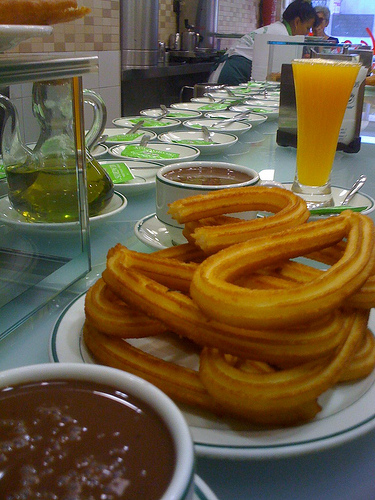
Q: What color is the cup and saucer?
A: White with a blue line.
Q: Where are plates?
A: On a table.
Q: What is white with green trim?
A: Plates.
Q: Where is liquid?
A: In a tall glass.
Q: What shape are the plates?
A: Round.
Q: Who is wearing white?
A: A woman.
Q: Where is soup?
A: In bowls.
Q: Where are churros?
A: On the plate.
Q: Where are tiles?
A: On the wall.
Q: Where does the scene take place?
A: In a large kitchen.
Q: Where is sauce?
A: In a bowl.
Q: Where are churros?
A: On plate.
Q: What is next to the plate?
A: Bowl.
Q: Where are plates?
A: On the table.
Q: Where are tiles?
A: On the wall.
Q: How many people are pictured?
A: Two.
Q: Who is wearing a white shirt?
A: A woman.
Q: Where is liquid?
A: In a glass.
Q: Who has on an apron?
A: Woman in white.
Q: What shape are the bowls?
A: Round.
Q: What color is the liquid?
A: Oil.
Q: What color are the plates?
A: White.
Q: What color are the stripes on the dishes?
A: Blue.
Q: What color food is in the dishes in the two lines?
A: Green.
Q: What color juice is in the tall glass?
A: Orange.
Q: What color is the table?
A: Blue.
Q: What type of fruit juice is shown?
A: Orange.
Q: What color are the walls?
A: White.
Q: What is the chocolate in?
A: Bowls.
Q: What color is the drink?
A: Orange.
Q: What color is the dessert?
A: Orange.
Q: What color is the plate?
A: White.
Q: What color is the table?
A: White.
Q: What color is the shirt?
A: White.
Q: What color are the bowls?
A: White.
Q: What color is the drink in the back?
A: Orange.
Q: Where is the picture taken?
A: Restaurant, indoors.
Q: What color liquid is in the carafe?
A: Green.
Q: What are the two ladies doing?
A: Talking.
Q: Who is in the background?
A: Two ladies.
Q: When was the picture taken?
A: Daytime.